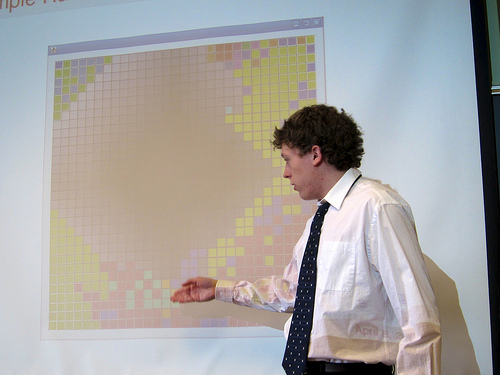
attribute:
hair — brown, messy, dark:
[268, 105, 365, 170]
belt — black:
[294, 359, 397, 374]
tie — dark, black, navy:
[281, 197, 336, 374]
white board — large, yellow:
[2, 2, 492, 374]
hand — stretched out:
[165, 274, 218, 306]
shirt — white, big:
[210, 162, 450, 372]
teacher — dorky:
[152, 94, 452, 372]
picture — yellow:
[59, 69, 288, 321]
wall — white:
[337, 11, 471, 138]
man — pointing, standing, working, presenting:
[157, 94, 444, 372]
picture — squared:
[230, 53, 280, 120]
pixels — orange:
[39, 29, 322, 336]